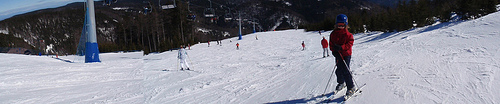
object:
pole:
[76, 0, 104, 65]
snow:
[4, 8, 498, 102]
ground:
[0, 7, 499, 102]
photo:
[1, 4, 498, 102]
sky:
[1, 1, 75, 21]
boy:
[323, 13, 376, 92]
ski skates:
[328, 82, 365, 100]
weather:
[0, 5, 498, 102]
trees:
[7, 0, 499, 55]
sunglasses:
[334, 20, 346, 27]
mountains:
[0, 0, 498, 64]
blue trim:
[83, 40, 101, 62]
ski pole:
[317, 59, 343, 99]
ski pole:
[339, 57, 357, 87]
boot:
[343, 81, 358, 99]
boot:
[331, 77, 346, 93]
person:
[230, 39, 240, 54]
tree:
[115, 11, 128, 51]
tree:
[131, 13, 141, 55]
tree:
[138, 13, 155, 54]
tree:
[155, 9, 171, 49]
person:
[173, 31, 190, 75]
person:
[300, 37, 308, 56]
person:
[316, 37, 334, 58]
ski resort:
[0, 1, 499, 101]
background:
[2, 2, 488, 58]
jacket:
[327, 21, 354, 59]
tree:
[117, 15, 131, 54]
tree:
[152, 2, 164, 51]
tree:
[172, 8, 185, 48]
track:
[168, 75, 249, 97]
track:
[244, 64, 298, 96]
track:
[409, 83, 462, 101]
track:
[437, 29, 482, 40]